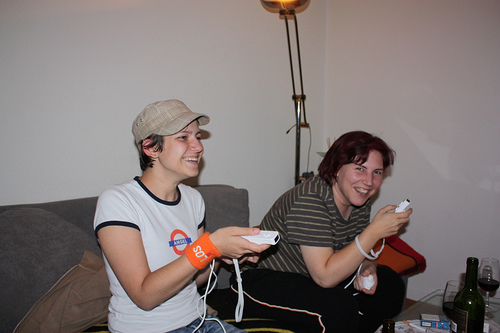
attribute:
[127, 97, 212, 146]
cap — tan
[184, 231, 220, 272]
wristband — orange, white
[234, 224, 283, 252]
game control — white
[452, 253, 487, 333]
bottle — dark, green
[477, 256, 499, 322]
wine glass — half-full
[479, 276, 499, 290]
wine — red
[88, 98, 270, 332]
woman — smiling, playing wii, happy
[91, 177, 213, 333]
shirt — white, black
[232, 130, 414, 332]
woman — smiling, playing wii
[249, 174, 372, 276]
shirt — striped, brown, white stri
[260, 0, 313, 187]
lamp — tall, on, metal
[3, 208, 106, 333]
cushion — grey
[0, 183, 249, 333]
sofa — grey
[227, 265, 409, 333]
pants — black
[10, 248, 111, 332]
jacket — brown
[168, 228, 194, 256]
logo — blue, orange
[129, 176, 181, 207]
trim — black